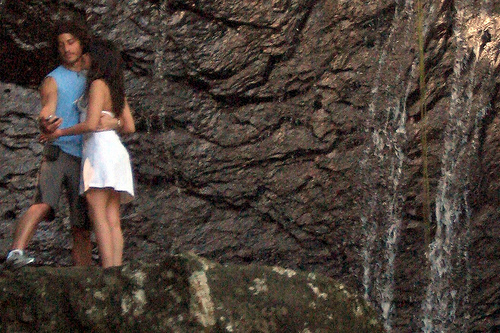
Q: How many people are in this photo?
A: Two.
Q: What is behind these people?
A: A rocky waterfall.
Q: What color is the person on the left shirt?
A: Blue.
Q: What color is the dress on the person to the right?
A: White.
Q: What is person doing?
A: Giving hug.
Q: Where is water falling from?
A: Rocks.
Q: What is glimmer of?
A: Sunlight.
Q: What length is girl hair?
A: Long.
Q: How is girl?
A: Dressed.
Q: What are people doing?
A: Taking picture.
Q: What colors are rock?
A: Gray and white.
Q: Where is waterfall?
A: In photo.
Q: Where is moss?
A: On rock.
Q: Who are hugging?
A: The couple.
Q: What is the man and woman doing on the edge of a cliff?
A: Embracing.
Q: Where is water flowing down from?
A: The side of the rocks.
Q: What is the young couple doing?
A: Posing for a photo.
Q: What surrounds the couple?
A: A black rock.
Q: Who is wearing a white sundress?
A: The woman.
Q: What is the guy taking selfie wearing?
A: A blue shirt.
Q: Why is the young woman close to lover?
A: Whispering in his ear.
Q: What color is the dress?
A: White.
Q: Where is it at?
A: On rocks.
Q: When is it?
A: Day time.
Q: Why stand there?
A: Taking photos.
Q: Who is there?
A: 2 people.